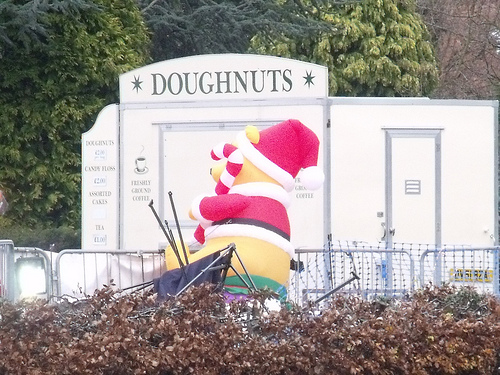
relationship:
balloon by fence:
[165, 118, 319, 313] [0, 240, 499, 339]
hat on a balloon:
[233, 116, 333, 201] [165, 118, 319, 313]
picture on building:
[142, 67, 329, 331] [75, 53, 499, 294]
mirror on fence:
[12, 257, 47, 304] [1, 244, 496, 308]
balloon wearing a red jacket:
[165, 118, 319, 313] [187, 181, 299, 253]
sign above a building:
[108, 52, 338, 284] [75, 53, 499, 294]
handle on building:
[388, 227, 393, 238] [319, 52, 499, 299]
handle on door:
[388, 227, 393, 238] [380, 125, 445, 296]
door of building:
[380, 125, 445, 296] [319, 52, 499, 299]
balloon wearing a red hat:
[165, 118, 319, 313] [248, 130, 319, 178]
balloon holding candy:
[165, 118, 319, 313] [210, 145, 240, 191]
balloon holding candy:
[165, 118, 319, 313] [210, 144, 241, 196]